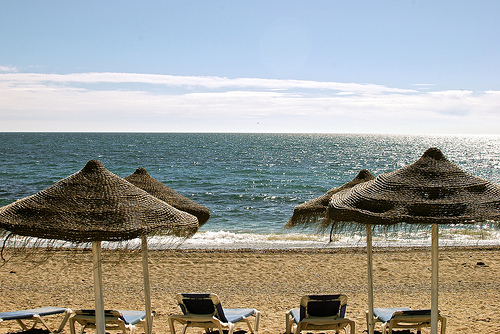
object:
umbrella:
[120, 166, 211, 333]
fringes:
[2, 228, 191, 263]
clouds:
[0, 65, 22, 73]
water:
[0, 131, 500, 251]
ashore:
[0, 246, 500, 334]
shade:
[342, 314, 391, 332]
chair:
[365, 308, 448, 334]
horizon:
[0, 129, 500, 138]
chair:
[75, 307, 145, 332]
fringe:
[318, 208, 497, 241]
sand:
[0, 244, 500, 333]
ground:
[0, 245, 500, 333]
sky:
[0, 0, 500, 133]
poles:
[429, 223, 439, 333]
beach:
[0, 243, 500, 333]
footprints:
[286, 276, 297, 283]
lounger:
[282, 291, 356, 333]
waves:
[0, 226, 500, 249]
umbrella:
[322, 146, 500, 334]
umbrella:
[283, 170, 379, 333]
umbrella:
[0, 159, 200, 333]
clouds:
[411, 81, 439, 91]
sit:
[373, 305, 414, 317]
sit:
[286, 306, 300, 323]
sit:
[224, 306, 258, 321]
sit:
[121, 305, 151, 332]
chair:
[2, 305, 76, 333]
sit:
[0, 307, 65, 315]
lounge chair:
[166, 291, 260, 334]